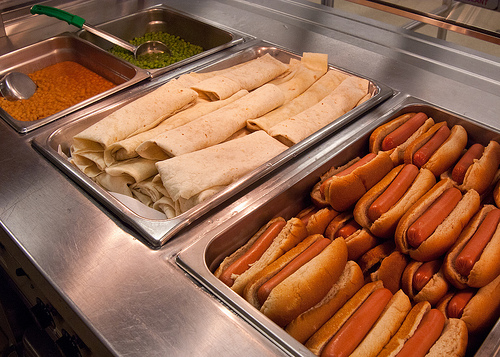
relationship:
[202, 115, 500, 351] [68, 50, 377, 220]
hotdogs near burritos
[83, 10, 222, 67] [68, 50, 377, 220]
peas near burritos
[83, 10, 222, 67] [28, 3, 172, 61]
peas near serving spoon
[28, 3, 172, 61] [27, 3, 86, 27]
serving spoon has handle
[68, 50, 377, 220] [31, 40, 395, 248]
burritos in tray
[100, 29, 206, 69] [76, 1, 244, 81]
peas in tray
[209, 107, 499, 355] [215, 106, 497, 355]
hot dogs in buns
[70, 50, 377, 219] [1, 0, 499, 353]
food in buffet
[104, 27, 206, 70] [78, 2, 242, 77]
peas in hot tray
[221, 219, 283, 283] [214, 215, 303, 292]
hot dog in bun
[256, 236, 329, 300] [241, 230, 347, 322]
hot dog in bun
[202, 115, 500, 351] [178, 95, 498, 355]
hotdogs in tray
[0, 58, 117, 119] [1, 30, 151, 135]
baked beans in tray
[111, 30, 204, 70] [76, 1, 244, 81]
peas in tray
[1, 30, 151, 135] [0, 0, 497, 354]
tray in counter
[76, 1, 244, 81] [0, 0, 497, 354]
tray in counter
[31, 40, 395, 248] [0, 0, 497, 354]
tray in counter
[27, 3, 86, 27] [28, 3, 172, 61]
handle on serving spoon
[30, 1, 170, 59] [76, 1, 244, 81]
untensil in tray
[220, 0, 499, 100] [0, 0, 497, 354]
ridges along edge of counter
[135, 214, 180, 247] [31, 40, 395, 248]
corner on tray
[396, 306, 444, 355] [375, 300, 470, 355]
hot dog in bun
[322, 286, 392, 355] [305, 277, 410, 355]
hot dog in bun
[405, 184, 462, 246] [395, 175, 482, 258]
hot dog in bun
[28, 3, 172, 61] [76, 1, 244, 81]
serving spoon in tray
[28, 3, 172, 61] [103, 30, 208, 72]
serving spoon in peas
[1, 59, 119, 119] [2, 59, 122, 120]
utensil in beans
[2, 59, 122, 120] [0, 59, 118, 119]
beans in sauce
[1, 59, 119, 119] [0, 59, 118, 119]
utensil in sauce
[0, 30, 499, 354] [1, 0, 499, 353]
fast food in buffet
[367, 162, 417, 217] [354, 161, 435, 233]
hotdog in bun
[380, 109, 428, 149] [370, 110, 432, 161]
hotdog in bun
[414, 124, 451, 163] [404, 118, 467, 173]
hotdog in bun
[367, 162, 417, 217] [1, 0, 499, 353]
hotdog on buffet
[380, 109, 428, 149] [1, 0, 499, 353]
hotdog on buffet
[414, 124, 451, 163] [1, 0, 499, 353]
hotdog on buffet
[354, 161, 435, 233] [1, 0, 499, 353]
bun on buffet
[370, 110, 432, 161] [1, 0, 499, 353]
bun on buffet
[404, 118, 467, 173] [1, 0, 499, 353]
bun on buffet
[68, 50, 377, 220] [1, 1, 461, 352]
burritos on table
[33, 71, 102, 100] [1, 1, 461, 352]
corn on table